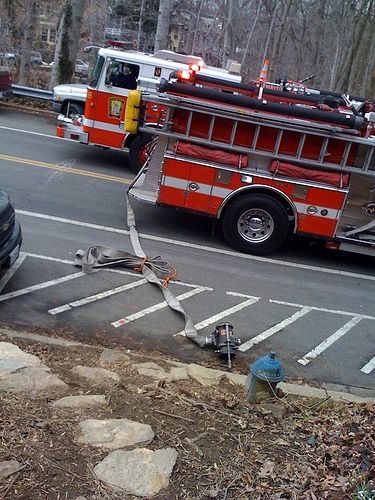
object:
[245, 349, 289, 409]
hydrant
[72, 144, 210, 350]
hose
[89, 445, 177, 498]
rock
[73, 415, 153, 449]
rock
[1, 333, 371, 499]
dirt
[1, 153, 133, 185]
line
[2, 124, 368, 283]
road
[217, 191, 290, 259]
tire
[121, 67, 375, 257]
engine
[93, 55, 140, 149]
door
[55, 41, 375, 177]
engine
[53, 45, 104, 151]
front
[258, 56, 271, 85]
cone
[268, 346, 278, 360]
bolt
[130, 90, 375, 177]
ladder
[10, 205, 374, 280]
line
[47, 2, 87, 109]
trees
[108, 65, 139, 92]
man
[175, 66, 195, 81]
lights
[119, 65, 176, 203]
end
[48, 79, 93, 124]
truck